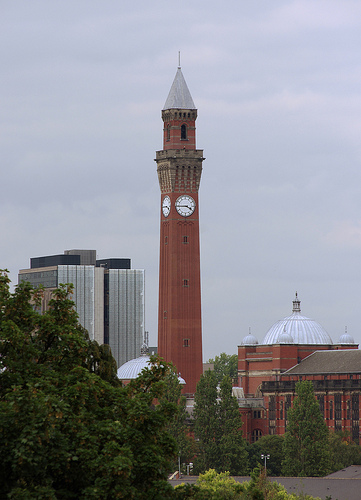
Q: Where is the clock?
A: On the tower.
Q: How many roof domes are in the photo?
A: Five.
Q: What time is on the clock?
A: A quarter to four.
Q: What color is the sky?
A: Gray.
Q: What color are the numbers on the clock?
A: Black.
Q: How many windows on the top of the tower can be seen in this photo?
A: Two.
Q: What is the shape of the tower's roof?
A: The shape of a cone.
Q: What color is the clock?
A: White.